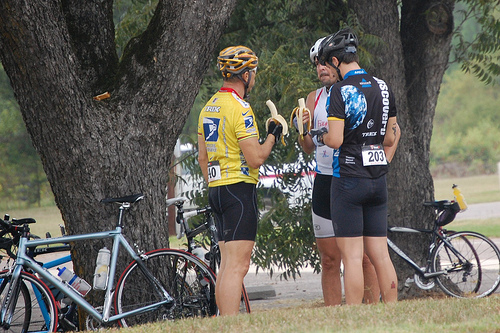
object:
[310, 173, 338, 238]
shorts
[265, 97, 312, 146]
bananas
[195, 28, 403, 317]
bikers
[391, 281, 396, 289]
tatoo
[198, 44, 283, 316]
man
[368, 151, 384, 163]
sticker 203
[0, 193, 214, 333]
bikes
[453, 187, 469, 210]
yellow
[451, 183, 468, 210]
bottle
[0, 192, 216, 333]
bike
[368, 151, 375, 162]
number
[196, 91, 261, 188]
yellow shirt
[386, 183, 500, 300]
bike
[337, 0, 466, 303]
tree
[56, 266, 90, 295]
bottle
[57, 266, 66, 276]
top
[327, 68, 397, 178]
black shirt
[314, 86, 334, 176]
shirt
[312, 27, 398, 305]
man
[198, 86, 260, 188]
shirt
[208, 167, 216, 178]
sticker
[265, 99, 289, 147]
banana